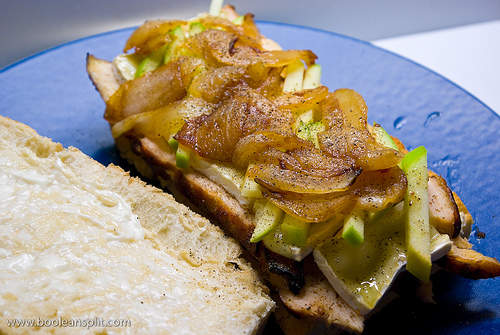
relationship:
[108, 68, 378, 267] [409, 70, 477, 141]
lunch on plate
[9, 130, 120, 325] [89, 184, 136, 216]
bread with butter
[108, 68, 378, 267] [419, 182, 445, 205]
lunch has pepper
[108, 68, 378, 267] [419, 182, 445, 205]
lunch with pepper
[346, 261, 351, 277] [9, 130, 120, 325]
cheese on bread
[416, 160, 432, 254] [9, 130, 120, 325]
apple on bread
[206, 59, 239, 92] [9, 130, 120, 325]
onions on bread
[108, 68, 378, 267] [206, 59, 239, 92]
lunch with onions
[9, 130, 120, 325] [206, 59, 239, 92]
bread by onions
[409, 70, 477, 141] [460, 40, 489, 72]
plate on table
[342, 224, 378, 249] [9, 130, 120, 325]
apples on bread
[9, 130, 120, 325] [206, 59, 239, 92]
bread with onions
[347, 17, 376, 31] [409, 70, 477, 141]
ground by plate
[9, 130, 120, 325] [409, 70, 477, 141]
bread on plate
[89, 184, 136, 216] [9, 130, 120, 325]
butter on bread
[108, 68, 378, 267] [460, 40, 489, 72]
lunch on table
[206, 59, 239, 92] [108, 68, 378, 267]
onions on lunch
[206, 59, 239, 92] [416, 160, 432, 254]
onions on apple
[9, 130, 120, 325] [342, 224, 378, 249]
bread with apples